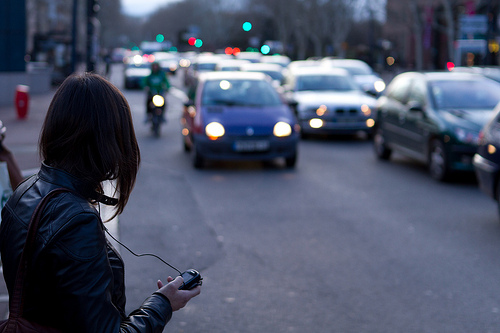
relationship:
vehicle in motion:
[184, 70, 297, 170] [182, 139, 296, 174]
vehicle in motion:
[284, 64, 371, 134] [301, 121, 374, 142]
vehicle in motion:
[376, 70, 479, 181] [371, 132, 472, 180]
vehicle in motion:
[147, 86, 169, 139] [149, 118, 165, 139]